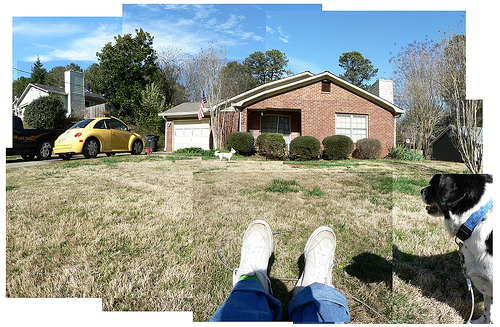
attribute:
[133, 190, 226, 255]
grass — dried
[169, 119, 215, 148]
door — white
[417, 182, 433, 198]
nose — black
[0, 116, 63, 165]
truck — black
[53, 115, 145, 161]
beetle — yellow 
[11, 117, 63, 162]
pickup — smaller, black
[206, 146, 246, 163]
dog — small, white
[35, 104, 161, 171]
beetle — Yellow 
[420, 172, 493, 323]
dog — black, white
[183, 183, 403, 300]
shoes — white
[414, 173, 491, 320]
sitting dog — white, black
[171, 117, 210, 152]
garage door — overhead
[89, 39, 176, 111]
tree — large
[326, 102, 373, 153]
window — large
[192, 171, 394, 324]
picture — pieced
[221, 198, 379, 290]
shoes — white